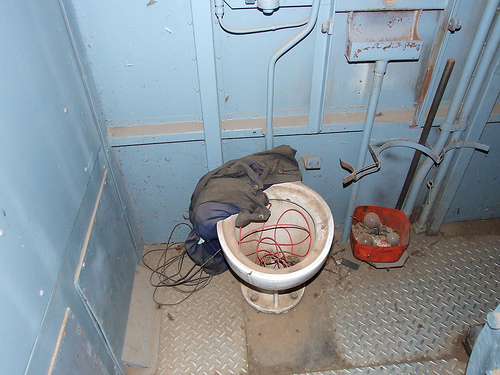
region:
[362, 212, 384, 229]
light bulb in the red bucket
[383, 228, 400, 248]
light bulb in the red bucket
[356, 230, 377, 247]
light bulb in the red bucket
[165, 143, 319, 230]
clothing on the white bucket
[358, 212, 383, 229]
light bulb in the bucket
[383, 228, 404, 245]
light bulb in the bucket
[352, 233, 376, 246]
light bulb in the bucket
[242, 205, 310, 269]
wires in the white bucket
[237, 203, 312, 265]
wires in the bucket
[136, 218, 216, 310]
wires on the floor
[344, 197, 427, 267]
dirty red bucket in photo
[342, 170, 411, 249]
dirty electrical bulbs in bucket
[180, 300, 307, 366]
dirty metal floor in photo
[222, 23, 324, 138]
water lines painted blue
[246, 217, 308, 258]
orange wires in toliet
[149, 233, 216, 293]
grey pile of wires on the ground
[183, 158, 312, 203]
dirty grey and blue cloth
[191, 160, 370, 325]
dirty base on white toliet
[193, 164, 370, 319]
dirty toliet with no lid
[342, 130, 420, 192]
metal clamps painted blue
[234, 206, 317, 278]
Red piece of wire in bucket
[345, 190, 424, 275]
Red square bucket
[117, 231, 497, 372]
Grey hardware floor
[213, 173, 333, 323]
White bucket on the ground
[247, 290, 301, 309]
Two silver bolts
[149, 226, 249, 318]
Grey wire on the floor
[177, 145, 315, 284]
Piece of blue and grey fabric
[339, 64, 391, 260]
Blue pole on the wall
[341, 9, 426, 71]
Blue box on the pole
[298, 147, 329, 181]
Small box on the wall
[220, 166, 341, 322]
Old toilet bowl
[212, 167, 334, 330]
Old toilet bowl with a red wire inside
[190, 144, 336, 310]
Old toilet bowl and an old cloth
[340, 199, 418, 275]
Bulbs inside a container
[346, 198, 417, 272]
Bulbs inside a red container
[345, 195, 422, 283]
Bulbs inside a container on the floor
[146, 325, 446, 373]
Old metal floor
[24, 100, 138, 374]
The inside of a blue metal building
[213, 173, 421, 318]
An old toilet bowl and red container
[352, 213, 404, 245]
old dusty white lightbulns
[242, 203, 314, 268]
red wires in a ceramic bowl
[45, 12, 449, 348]
walls painted light blue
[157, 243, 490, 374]
silver steel floor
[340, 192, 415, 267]
plastic red bucket on the ground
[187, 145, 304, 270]
old piece of dusty clothing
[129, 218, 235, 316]
black wires on the ground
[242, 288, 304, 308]
bolts attaching item to floor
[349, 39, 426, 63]
paint chipping from wall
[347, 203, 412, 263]
Three light bulbs in orange container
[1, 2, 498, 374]
Unfinished rest room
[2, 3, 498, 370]
Dirty and unfinished rest room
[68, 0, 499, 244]
Exposed plumbing on the wall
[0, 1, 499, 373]
Dirty blue wall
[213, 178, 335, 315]
Dusty toilet bowl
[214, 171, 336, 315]
Unusable toilet bowl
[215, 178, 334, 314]
Dirty toilet base with wire inside.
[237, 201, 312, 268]
Red wire inside a toilet base.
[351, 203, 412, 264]
Orange container full of light bulbs and junk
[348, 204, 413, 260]
Dirty orange container with light bulbs inside.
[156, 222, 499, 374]
A metal dirty floor.